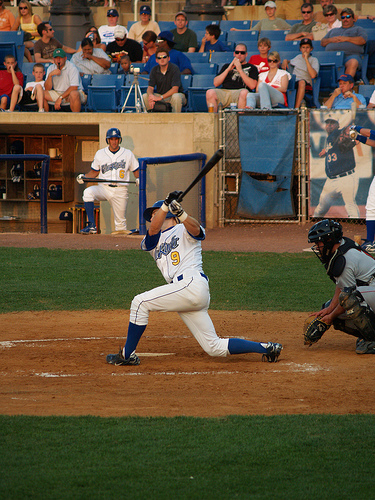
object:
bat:
[207, 149, 224, 170]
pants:
[128, 270, 232, 360]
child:
[8, 64, 46, 112]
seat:
[18, 59, 57, 110]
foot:
[106, 349, 141, 365]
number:
[119, 169, 125, 179]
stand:
[120, 79, 149, 114]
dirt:
[2, 215, 373, 246]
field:
[1, 229, 372, 388]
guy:
[142, 48, 188, 114]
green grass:
[0, 414, 373, 499]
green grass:
[0, 246, 342, 309]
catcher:
[301, 218, 374, 357]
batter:
[115, 196, 280, 364]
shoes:
[106, 347, 140, 366]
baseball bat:
[176, 148, 223, 203]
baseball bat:
[81, 177, 136, 184]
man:
[76, 126, 140, 234]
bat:
[81, 177, 92, 182]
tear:
[242, 170, 289, 193]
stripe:
[133, 275, 194, 325]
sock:
[226, 338, 265, 356]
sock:
[123, 320, 148, 356]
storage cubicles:
[0, 134, 78, 203]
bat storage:
[69, 206, 100, 233]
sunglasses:
[156, 55, 168, 59]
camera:
[130, 65, 141, 76]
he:
[106, 190, 283, 367]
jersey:
[140, 223, 206, 283]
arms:
[328, 277, 356, 324]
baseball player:
[75, 128, 139, 237]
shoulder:
[140, 234, 156, 252]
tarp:
[224, 109, 303, 215]